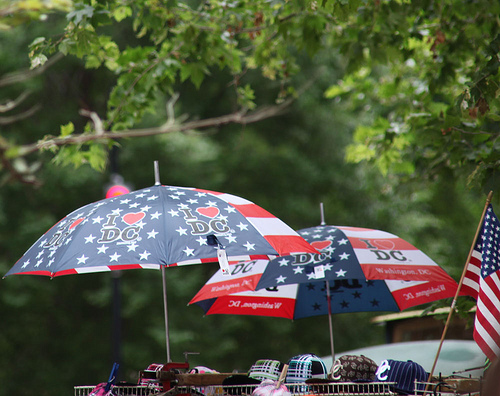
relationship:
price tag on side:
[216, 247, 233, 278] [166, 231, 284, 274]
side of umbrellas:
[166, 231, 284, 274] [3, 158, 325, 367]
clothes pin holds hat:
[277, 364, 290, 389] [248, 380, 292, 395]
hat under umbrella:
[282, 354, 327, 392] [186, 201, 471, 363]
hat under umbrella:
[306, 355, 379, 386] [186, 201, 471, 363]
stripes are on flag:
[462, 253, 499, 364] [452, 205, 500, 364]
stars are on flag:
[479, 204, 500, 275] [452, 205, 500, 364]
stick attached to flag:
[421, 187, 493, 383] [452, 205, 500, 364]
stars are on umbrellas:
[163, 188, 192, 259] [3, 158, 325, 367]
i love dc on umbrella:
[357, 236, 407, 263] [186, 201, 471, 363]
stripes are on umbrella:
[337, 226, 457, 286] [186, 201, 471, 363]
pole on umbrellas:
[160, 263, 172, 366] [3, 158, 325, 367]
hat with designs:
[306, 355, 379, 386] [348, 361, 367, 380]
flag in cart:
[452, 205, 500, 364] [73, 365, 499, 395]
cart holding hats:
[73, 365, 499, 395] [324, 355, 428, 393]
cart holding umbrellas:
[73, 365, 499, 395] [3, 156, 463, 368]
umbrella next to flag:
[186, 201, 471, 363] [452, 205, 500, 364]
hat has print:
[306, 355, 379, 386] [353, 361, 364, 380]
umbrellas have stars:
[3, 156, 463, 368] [163, 188, 192, 259]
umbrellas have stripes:
[3, 156, 463, 368] [337, 226, 457, 286]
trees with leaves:
[0, 0, 500, 191] [355, 121, 418, 172]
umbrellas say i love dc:
[3, 156, 463, 368] [181, 200, 228, 236]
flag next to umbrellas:
[452, 205, 500, 364] [3, 156, 463, 368]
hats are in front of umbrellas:
[324, 355, 428, 393] [3, 156, 463, 368]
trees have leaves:
[0, 0, 500, 191] [355, 121, 418, 172]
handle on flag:
[422, 297, 456, 387] [452, 205, 500, 364]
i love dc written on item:
[97, 210, 149, 244] [18, 185, 322, 278]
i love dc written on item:
[181, 200, 228, 236] [18, 185, 322, 278]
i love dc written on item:
[357, 236, 407, 263] [194, 226, 458, 316]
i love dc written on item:
[41, 216, 83, 253] [18, 185, 322, 278]